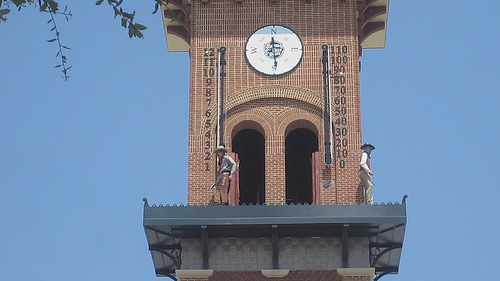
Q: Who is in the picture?
A: Cowboys.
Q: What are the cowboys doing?
A: Standing.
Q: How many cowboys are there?
A: Two.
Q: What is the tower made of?
A: Brick.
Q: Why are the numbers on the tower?
A: Clock.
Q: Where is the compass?
A: On the tower.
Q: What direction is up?
A: North.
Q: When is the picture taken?
A: Day time.